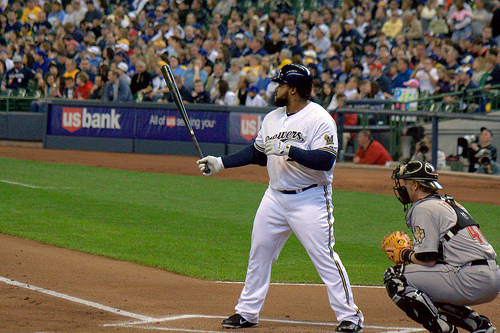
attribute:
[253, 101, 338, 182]
shirt — white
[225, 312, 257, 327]
cleats — black, white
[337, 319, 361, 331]
cleats — white, black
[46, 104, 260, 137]
banner — blue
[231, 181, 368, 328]
pants — white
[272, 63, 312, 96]
helmet — black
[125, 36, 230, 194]
bat — black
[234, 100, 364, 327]
uniform — white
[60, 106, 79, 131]
shield — red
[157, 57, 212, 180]
bat — black, wood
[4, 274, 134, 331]
lines — white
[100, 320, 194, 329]
lines — white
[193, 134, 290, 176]
gloves — white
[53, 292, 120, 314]
base line — white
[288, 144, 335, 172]
sleeve — navy blue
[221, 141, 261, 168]
sleeve — navy blue, white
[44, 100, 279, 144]
tarp — blue